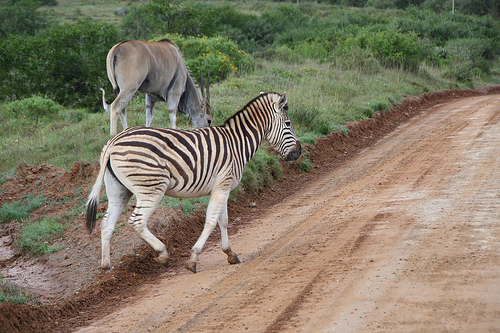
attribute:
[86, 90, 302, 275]
zebra — striped, black, white, walking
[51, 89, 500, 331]
dirt road — paved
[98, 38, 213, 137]
antelope — not striped, grey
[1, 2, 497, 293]
grass — green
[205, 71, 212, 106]
horn — pointed, small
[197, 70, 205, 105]
horn — small, pointed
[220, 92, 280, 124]
mane — black, short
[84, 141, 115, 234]
tail — long